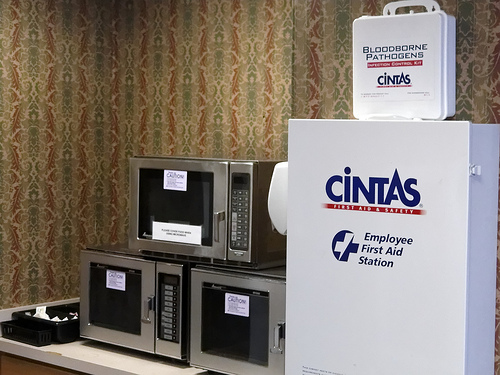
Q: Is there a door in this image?
A: Yes, there is a door.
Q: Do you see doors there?
A: Yes, there is a door.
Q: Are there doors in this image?
A: Yes, there is a door.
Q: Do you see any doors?
A: Yes, there is a door.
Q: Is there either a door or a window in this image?
A: Yes, there is a door.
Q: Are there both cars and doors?
A: No, there is a door but no cars.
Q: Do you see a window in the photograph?
A: No, there are no windows.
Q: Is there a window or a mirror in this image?
A: No, there are no windows or mirrors.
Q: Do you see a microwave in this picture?
A: Yes, there is a microwave.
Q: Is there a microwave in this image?
A: Yes, there is a microwave.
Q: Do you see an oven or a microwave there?
A: Yes, there is a microwave.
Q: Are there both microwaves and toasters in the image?
A: No, there is a microwave but no toasters.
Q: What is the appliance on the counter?
A: The appliance is a microwave.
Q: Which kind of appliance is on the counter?
A: The appliance is a microwave.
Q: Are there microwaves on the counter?
A: Yes, there is a microwave on the counter.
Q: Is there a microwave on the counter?
A: Yes, there is a microwave on the counter.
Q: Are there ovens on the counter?
A: No, there is a microwave on the counter.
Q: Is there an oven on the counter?
A: No, there is a microwave on the counter.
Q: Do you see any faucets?
A: No, there are no faucets.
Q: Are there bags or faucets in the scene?
A: No, there are no faucets or bags.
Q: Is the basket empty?
A: Yes, the basket is empty.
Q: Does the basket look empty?
A: Yes, the basket is empty.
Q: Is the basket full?
A: No, the basket is empty.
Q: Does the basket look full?
A: No, the basket is empty.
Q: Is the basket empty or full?
A: The basket is empty.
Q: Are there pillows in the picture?
A: No, there are no pillows.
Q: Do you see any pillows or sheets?
A: No, there are no pillows or sheets.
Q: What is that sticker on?
A: The sticker is on the microwave.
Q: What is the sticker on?
A: The sticker is on the microwave.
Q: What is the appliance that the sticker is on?
A: The appliance is a microwave.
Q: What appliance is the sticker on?
A: The sticker is on the microwave.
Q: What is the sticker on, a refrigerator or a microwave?
A: The sticker is on a microwave.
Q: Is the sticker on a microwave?
A: Yes, the sticker is on a microwave.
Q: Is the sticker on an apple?
A: No, the sticker is on a microwave.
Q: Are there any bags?
A: No, there are no bags.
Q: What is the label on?
A: The label is on the microwave.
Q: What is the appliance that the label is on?
A: The appliance is a microwave.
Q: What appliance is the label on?
A: The label is on the microwave.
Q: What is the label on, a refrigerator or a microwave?
A: The label is on a microwave.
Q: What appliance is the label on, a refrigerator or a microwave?
A: The label is on a microwave.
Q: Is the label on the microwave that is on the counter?
A: Yes, the label is on the microwave.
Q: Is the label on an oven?
A: No, the label is on the microwave.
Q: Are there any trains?
A: No, there are no trains.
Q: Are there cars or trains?
A: No, there are no trains or cars.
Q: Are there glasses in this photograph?
A: No, there are no glasses.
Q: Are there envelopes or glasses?
A: No, there are no glasses or envelopes.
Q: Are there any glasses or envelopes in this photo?
A: No, there are no glasses or envelopes.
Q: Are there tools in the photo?
A: No, there are no tools.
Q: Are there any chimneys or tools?
A: No, there are no tools or chimneys.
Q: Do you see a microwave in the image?
A: Yes, there is a microwave.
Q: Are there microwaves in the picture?
A: Yes, there is a microwave.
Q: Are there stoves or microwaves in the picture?
A: Yes, there is a microwave.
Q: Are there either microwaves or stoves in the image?
A: Yes, there is a microwave.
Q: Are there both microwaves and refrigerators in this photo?
A: No, there is a microwave but no refrigerators.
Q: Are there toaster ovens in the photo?
A: No, there are no toaster ovens.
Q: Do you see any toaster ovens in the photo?
A: No, there are no toaster ovens.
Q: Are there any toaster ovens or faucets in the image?
A: No, there are no toaster ovens or faucets.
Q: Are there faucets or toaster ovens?
A: No, there are no toaster ovens or faucets.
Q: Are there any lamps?
A: No, there are no lamps.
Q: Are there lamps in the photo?
A: No, there are no lamps.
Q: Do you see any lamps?
A: No, there are no lamps.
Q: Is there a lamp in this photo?
A: No, there are no lamps.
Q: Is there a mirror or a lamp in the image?
A: No, there are no lamps or mirrors.